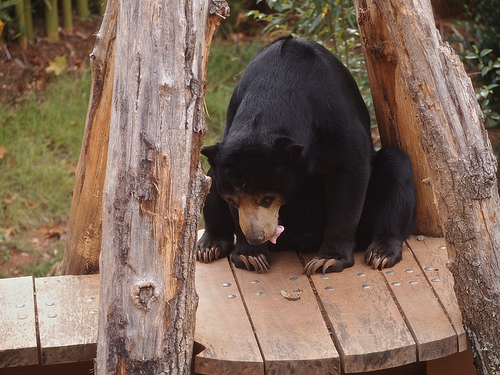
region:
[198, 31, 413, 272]
Black bear on a wooden bridge.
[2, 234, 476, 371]
Wooden bridge in between four trunks.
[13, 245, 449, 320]
Metal screws used on the bridge.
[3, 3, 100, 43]
Small bamboo like trees in the background.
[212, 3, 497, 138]
Leave green shrubs in the background.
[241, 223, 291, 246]
Black bear eating something.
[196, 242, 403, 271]
Large, long claws on the bear.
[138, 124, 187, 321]
Parts of the tree trunks peeling off.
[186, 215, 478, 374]
Oval shaped bridge in between the trunks.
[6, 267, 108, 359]
Rectangular boards off to the side.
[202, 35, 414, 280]
black bear sitting on wood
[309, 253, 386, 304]
wood plank under bear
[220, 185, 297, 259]
light color face on bear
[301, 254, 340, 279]
nails on bear paw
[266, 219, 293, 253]
food in bear mouth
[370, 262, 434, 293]
metal bolts in wood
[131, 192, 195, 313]
log with bark rubbed off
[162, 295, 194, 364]
tree bark on log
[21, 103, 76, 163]
green grass on ground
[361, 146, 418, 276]
back leg of bear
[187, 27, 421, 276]
A small black bear sitting on a wooden platform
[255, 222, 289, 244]
A small pink thing in the bear's mouth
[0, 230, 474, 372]
A manmade wooden platform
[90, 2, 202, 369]
Damaged tree trunk or log holding the platform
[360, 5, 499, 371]
Another trunk or log curving over the platform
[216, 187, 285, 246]
The black bear's pale face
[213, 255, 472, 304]
Smooth screws or nails in the wooden platform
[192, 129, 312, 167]
The bear's small fuzzy black ears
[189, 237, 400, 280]
The bear's long, pale claws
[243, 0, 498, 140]
A leafy green bush behind the platofrm and bear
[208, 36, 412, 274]
black bear with pink tongue sticking out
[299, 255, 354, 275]
long sharp brown nails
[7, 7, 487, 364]
wooden bridge for bear enclosure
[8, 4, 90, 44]
five green bamboo trunks in the ground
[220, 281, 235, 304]
round metal screws in wood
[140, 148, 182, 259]
scratch marks on brown log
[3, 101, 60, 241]
green grass on the ground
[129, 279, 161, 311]
circular knot in the wood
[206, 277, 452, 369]
planks of wood hooked together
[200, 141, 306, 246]
black bear with brown face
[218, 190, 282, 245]
light brown snout on black bear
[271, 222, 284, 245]
pink tongue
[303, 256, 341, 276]
bear has big sharp claws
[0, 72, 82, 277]
grass behind bear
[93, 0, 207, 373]
wood log next to bear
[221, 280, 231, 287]
metal studs in wood slat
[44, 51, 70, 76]
dry leaf on grass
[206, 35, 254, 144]
grass is green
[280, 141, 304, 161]
ear on bear's head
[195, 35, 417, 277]
bear is climbing on to wood structure